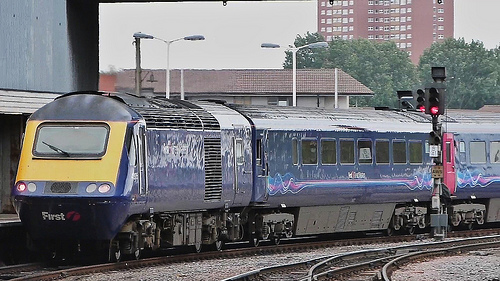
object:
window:
[32, 122, 109, 157]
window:
[406, 139, 423, 166]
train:
[8, 90, 499, 264]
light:
[429, 106, 439, 116]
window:
[299, 138, 317, 165]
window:
[318, 137, 338, 166]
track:
[307, 233, 500, 281]